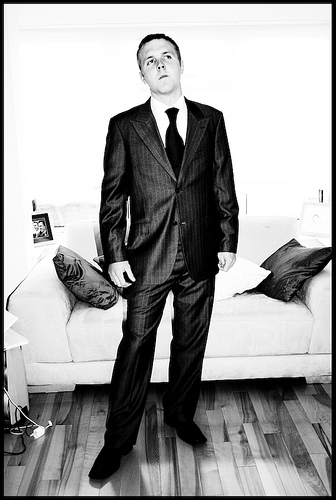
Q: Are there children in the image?
A: No, there are no children.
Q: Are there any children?
A: No, there are no children.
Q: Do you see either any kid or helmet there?
A: No, there are no children or helmets.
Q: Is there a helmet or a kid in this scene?
A: No, there are no children or helmets.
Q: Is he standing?
A: Yes, the man is standing.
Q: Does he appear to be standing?
A: Yes, the man is standing.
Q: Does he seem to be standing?
A: Yes, the man is standing.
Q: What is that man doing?
A: The man is standing.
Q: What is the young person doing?
A: The man is standing.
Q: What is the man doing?
A: The man is standing.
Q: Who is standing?
A: The man is standing.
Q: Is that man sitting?
A: No, the man is standing.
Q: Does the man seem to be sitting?
A: No, the man is standing.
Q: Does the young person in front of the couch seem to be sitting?
A: No, the man is standing.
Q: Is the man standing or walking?
A: The man is standing.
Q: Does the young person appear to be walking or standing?
A: The man is standing.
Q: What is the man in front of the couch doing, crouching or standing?
A: The man is standing.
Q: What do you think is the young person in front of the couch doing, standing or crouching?
A: The man is standing.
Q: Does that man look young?
A: Yes, the man is young.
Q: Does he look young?
A: Yes, the man is young.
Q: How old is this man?
A: The man is young.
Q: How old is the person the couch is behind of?
A: The man is young.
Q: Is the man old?
A: No, the man is young.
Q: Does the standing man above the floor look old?
A: No, the man is young.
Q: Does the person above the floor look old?
A: No, the man is young.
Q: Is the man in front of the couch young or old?
A: The man is young.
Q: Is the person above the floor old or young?
A: The man is young.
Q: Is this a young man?
A: Yes, this is a young man.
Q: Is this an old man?
A: No, this is a young man.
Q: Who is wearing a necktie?
A: The man is wearing a necktie.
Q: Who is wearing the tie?
A: The man is wearing a necktie.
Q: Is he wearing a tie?
A: Yes, the man is wearing a tie.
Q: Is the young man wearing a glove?
A: No, the man is wearing a tie.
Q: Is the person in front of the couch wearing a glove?
A: No, the man is wearing a tie.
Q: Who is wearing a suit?
A: The man is wearing a suit.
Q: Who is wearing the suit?
A: The man is wearing a suit.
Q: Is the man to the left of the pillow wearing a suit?
A: Yes, the man is wearing a suit.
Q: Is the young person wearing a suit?
A: Yes, the man is wearing a suit.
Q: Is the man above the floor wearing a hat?
A: No, the man is wearing a suit.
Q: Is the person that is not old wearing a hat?
A: No, the man is wearing a suit.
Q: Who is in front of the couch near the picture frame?
A: The man is in front of the couch.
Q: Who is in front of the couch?
A: The man is in front of the couch.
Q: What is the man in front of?
A: The man is in front of the couch.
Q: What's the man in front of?
A: The man is in front of the couch.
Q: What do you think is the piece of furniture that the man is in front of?
A: The piece of furniture is a couch.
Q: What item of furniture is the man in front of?
A: The man is in front of the couch.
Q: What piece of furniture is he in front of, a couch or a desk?
A: The man is in front of a couch.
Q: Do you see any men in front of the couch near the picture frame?
A: Yes, there is a man in front of the couch.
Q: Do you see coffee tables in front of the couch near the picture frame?
A: No, there is a man in front of the couch.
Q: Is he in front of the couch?
A: Yes, the man is in front of the couch.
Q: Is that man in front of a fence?
A: No, the man is in front of the couch.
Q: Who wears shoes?
A: The man wears shoes.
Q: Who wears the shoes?
A: The man wears shoes.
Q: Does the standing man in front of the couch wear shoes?
A: Yes, the man wears shoes.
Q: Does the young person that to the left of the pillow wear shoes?
A: Yes, the man wears shoes.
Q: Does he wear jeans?
A: No, the man wears shoes.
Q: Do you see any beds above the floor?
A: No, there is a man above the floor.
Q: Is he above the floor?
A: Yes, the man is above the floor.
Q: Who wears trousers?
A: The man wears trousers.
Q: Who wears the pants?
A: The man wears trousers.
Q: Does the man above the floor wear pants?
A: Yes, the man wears pants.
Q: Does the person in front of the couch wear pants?
A: Yes, the man wears pants.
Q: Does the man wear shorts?
A: No, the man wears pants.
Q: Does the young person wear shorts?
A: No, the man wears pants.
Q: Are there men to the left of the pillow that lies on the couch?
A: Yes, there is a man to the left of the pillow.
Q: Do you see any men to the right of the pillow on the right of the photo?
A: No, the man is to the left of the pillow.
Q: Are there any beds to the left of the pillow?
A: No, there is a man to the left of the pillow.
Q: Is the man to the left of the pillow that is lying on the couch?
A: Yes, the man is to the left of the pillow.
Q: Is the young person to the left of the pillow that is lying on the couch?
A: Yes, the man is to the left of the pillow.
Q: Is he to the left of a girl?
A: No, the man is to the left of the pillow.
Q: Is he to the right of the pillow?
A: No, the man is to the left of the pillow.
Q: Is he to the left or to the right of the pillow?
A: The man is to the left of the pillow.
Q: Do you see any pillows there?
A: Yes, there is a pillow.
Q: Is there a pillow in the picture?
A: Yes, there is a pillow.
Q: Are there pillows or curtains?
A: Yes, there is a pillow.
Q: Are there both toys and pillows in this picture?
A: No, there is a pillow but no toys.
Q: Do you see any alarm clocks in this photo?
A: No, there are no alarm clocks.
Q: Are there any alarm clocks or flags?
A: No, there are no alarm clocks or flags.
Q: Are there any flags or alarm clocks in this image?
A: No, there are no alarm clocks or flags.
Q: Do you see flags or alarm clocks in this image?
A: No, there are no alarm clocks or flags.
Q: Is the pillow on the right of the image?
A: Yes, the pillow is on the right of the image.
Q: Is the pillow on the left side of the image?
A: No, the pillow is on the right of the image.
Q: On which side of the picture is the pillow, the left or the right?
A: The pillow is on the right of the image.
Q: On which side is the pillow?
A: The pillow is on the right of the image.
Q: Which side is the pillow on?
A: The pillow is on the right of the image.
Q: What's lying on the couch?
A: The pillow is lying on the couch.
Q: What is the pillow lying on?
A: The pillow is lying on the couch.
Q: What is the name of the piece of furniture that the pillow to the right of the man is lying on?
A: The piece of furniture is a couch.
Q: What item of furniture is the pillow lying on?
A: The pillow is lying on the couch.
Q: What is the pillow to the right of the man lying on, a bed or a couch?
A: The pillow is lying on a couch.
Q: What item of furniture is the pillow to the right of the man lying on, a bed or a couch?
A: The pillow is lying on a couch.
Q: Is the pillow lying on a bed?
A: No, the pillow is lying on a couch.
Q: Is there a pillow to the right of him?
A: Yes, there is a pillow to the right of the man.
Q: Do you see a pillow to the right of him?
A: Yes, there is a pillow to the right of the man.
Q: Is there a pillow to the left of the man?
A: No, the pillow is to the right of the man.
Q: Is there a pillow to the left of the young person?
A: No, the pillow is to the right of the man.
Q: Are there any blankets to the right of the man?
A: No, there is a pillow to the right of the man.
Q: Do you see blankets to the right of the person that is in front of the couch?
A: No, there is a pillow to the right of the man.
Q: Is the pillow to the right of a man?
A: Yes, the pillow is to the right of a man.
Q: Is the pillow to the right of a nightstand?
A: No, the pillow is to the right of a man.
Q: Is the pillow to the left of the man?
A: No, the pillow is to the right of the man.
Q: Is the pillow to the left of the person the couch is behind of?
A: No, the pillow is to the right of the man.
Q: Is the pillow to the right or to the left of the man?
A: The pillow is to the right of the man.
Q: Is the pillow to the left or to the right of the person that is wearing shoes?
A: The pillow is to the right of the man.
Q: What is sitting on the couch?
A: The pillow is sitting on the couch.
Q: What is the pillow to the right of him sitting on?
A: The pillow is sitting on the couch.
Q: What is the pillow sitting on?
A: The pillow is sitting on the couch.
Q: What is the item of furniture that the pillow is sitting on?
A: The piece of furniture is a couch.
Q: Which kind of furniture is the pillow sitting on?
A: The pillow is sitting on the couch.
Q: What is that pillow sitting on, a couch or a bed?
A: The pillow is sitting on a couch.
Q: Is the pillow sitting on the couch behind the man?
A: Yes, the pillow is sitting on the couch.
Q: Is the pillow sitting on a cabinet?
A: No, the pillow is sitting on the couch.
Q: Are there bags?
A: No, there are no bags.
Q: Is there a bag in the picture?
A: No, there are no bags.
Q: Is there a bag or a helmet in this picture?
A: No, there are no bags or helmets.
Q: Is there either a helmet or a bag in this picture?
A: No, there are no bags or helmets.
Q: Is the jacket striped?
A: Yes, the jacket is striped.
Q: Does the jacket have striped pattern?
A: Yes, the jacket is striped.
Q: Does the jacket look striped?
A: Yes, the jacket is striped.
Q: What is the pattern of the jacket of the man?
A: The jacket is striped.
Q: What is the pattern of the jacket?
A: The jacket is striped.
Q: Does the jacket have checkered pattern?
A: No, the jacket is striped.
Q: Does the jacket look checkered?
A: No, the jacket is striped.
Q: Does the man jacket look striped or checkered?
A: The jacket is striped.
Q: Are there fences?
A: No, there are no fences.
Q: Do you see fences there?
A: No, there are no fences.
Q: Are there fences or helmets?
A: No, there are no fences or helmets.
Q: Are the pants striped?
A: Yes, the pants are striped.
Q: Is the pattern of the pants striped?
A: Yes, the pants are striped.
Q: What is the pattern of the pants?
A: The pants are striped.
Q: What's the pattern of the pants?
A: The pants are striped.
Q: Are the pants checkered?
A: No, the pants are striped.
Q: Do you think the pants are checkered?
A: No, the pants are striped.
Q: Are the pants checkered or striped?
A: The pants are striped.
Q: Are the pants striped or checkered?
A: The pants are striped.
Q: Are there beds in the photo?
A: No, there are no beds.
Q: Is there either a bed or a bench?
A: No, there are no beds or benches.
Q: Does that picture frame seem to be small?
A: Yes, the picture frame is small.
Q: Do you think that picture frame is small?
A: Yes, the picture frame is small.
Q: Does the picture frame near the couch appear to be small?
A: Yes, the picture frame is small.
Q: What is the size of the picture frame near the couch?
A: The picture frame is small.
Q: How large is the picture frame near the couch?
A: The picture frame is small.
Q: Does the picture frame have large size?
A: No, the picture frame is small.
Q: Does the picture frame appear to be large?
A: No, the picture frame is small.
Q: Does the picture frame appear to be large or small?
A: The picture frame is small.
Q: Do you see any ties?
A: Yes, there is a tie.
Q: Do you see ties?
A: Yes, there is a tie.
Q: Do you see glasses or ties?
A: Yes, there is a tie.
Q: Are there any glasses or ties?
A: Yes, there is a tie.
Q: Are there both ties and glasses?
A: No, there is a tie but no glasses.